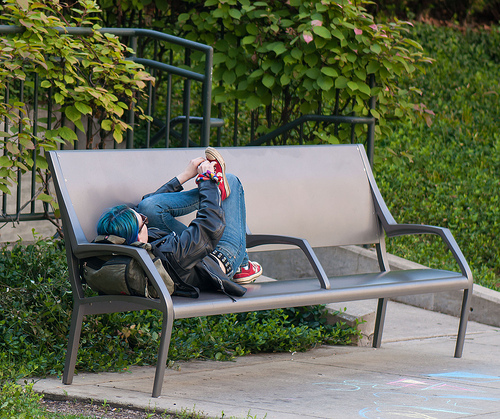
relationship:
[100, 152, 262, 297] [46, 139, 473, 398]
woman laying on bench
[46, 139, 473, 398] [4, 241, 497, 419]
bench on top of sidewalk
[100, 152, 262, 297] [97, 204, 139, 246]
woman has hair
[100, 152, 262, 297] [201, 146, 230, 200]
woman tying her shoe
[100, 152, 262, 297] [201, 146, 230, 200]
woman wearing shoe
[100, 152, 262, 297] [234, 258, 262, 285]
woman wearing shoe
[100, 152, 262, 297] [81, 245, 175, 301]
woman laying on her backpack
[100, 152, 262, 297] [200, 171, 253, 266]
woman wears blue jeans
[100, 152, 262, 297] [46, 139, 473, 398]
woman lying on bench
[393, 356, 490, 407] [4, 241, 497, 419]
chalk on top of sidewalk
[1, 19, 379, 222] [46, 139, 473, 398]
staircase behind bench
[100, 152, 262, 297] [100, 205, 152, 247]
woman resting head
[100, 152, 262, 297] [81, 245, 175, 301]
woman resting on backpack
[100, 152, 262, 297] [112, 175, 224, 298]
woman wearing leather jacket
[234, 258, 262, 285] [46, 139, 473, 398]
shoe resting on bench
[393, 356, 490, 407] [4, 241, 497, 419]
chalk drawn on sidewalk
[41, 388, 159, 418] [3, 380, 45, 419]
dirt patch has grass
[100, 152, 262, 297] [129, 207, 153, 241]
woman has face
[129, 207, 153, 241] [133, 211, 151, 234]
face has glasses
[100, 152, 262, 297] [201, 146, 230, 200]
woman tying shoe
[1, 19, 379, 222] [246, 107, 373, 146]
staircase has hand rail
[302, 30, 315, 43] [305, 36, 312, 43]
leaf has tip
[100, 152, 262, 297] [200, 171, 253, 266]
woman wearing blue jeans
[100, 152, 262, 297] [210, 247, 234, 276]
woman wearing belt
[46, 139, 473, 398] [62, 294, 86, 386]
bench has leg